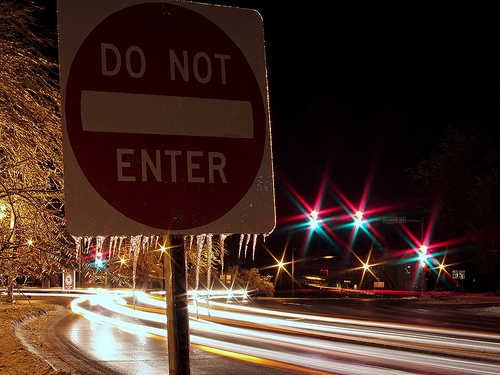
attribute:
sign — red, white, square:
[57, 1, 287, 374]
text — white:
[97, 41, 233, 90]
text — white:
[113, 145, 240, 190]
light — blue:
[305, 208, 327, 236]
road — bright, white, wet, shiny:
[215, 295, 417, 374]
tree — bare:
[5, 13, 58, 273]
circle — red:
[118, 11, 194, 46]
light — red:
[354, 213, 360, 230]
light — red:
[416, 242, 435, 262]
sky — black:
[276, 6, 497, 149]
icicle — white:
[199, 236, 207, 271]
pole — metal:
[166, 240, 192, 373]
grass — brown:
[9, 361, 27, 374]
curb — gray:
[14, 321, 66, 356]